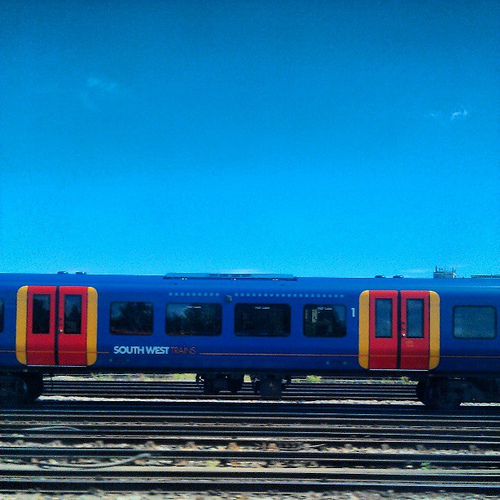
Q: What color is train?
A: Blue.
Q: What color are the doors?
A: Red and yellow.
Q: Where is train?
A: Track.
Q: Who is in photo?
A: Noone.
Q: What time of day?
A: Daytime.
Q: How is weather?
A: Clear.